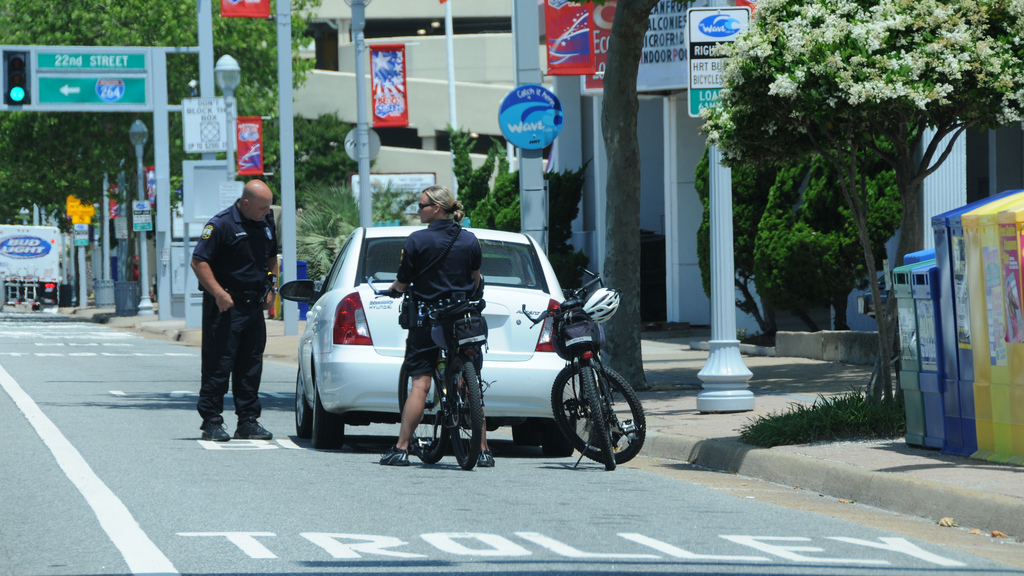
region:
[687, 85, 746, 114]
sign on the pole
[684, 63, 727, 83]
sign on the pole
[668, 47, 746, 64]
sign on the pole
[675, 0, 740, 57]
sign on the pole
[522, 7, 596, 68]
sign on the pole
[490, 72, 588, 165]
sign on the pole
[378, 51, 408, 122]
sign on the pole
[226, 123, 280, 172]
sign on the pole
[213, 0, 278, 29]
sign on the pole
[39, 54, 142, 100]
sign on the pole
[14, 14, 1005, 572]
picture taken outdoors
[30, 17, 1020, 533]
picture taken during the day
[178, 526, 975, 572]
the word trolley on the road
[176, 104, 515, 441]
two police officers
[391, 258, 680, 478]
two police officer bicycles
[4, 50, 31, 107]
the signal light shows green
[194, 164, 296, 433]
the male police officer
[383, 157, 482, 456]
the female police officer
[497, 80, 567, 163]
a blue and light blue sign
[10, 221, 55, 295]
a bud light truck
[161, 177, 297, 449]
man is standing in the street by a car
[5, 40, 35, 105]
traffic light is showing green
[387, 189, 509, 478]
woman is on a bicycle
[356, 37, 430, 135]
red white and blue flag on the pole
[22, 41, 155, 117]
green street sign on the pole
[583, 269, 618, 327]
helmet hanging on the bike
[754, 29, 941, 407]
small tree on the sidewalk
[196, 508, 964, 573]
white letters painted in the street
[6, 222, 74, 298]
beer delivery truck parked up the street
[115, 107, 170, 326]
light post on the sidewalk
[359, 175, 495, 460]
woman cop in black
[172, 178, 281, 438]
cop in black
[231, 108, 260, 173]
red and blue colored signs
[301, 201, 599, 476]
a car that is white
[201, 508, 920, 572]
a word on the road that is white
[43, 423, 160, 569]
a line that is white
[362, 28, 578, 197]
a building that is white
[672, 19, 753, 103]
a small sign that is white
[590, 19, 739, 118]
a large sign that is white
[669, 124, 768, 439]
a large pole that is white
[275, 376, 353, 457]
a wheel that is black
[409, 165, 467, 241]
the head of an officer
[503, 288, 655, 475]
a bike that is black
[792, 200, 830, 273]
green leaves on the tree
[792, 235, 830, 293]
green leaves on the tree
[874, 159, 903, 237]
green leaves on the tree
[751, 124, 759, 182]
green leaves on the tree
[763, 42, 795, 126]
green leaves on the tree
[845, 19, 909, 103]
green leaves on the tree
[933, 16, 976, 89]
green leaves on the tree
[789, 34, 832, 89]
green leaves on the tree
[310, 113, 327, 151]
green leaves on the tree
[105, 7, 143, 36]
green leaves on the tree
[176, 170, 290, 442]
The policeman standing beside the car.